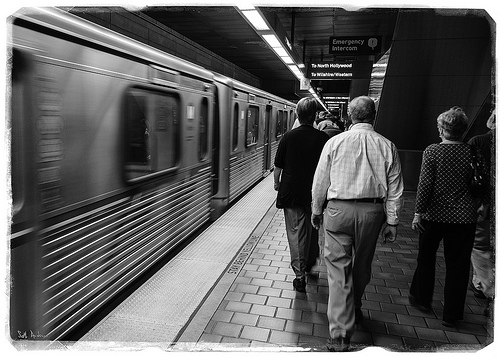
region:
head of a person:
[340, 94, 382, 132]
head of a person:
[429, 110, 474, 143]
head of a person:
[290, 93, 331, 130]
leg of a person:
[316, 210, 391, 345]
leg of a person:
[404, 210, 441, 320]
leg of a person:
[447, 203, 489, 325]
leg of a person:
[277, 180, 326, 291]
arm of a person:
[305, 127, 342, 224]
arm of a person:
[382, 144, 413, 238]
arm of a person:
[412, 141, 445, 243]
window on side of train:
[112, 71, 197, 192]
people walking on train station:
[274, 77, 493, 342]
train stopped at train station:
[21, 8, 301, 303]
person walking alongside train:
[317, 109, 344, 142]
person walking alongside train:
[411, 90, 491, 328]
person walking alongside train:
[304, 96, 415, 340]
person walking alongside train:
[281, 89, 322, 299]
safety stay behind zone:
[156, 200, 271, 339]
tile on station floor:
[257, 270, 284, 307]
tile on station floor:
[219, 285, 244, 299]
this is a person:
[320, 98, 408, 349]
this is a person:
[398, 106, 481, 334]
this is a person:
[264, 62, 357, 319]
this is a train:
[6, 29, 298, 345]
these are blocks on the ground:
[227, 289, 257, 329]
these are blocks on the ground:
[244, 256, 305, 336]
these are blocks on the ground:
[235, 292, 297, 348]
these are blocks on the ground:
[370, 278, 427, 335]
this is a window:
[120, 89, 187, 184]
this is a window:
[195, 97, 212, 162]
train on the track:
[8, 35, 280, 205]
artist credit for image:
[16, 320, 56, 344]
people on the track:
[268, 90, 463, 339]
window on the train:
[122, 89, 177, 162]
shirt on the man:
[323, 123, 387, 207]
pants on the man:
[321, 200, 378, 332]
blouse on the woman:
[423, 143, 471, 220]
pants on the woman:
[418, 217, 458, 307]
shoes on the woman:
[398, 293, 458, 327]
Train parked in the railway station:
[43, 15, 225, 165]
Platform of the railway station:
[191, 273, 276, 329]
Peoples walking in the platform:
[263, 88, 479, 344]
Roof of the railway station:
[216, 8, 330, 50]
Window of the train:
[121, 83, 186, 190]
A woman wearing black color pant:
[418, 222, 478, 314]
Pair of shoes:
[314, 297, 369, 354]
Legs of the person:
[324, 244, 377, 276]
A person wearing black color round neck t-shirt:
[273, 124, 330, 172]